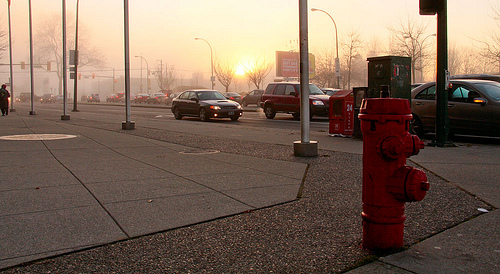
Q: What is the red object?
A: A fire hydrant.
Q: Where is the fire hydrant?
A: On the sidewalk.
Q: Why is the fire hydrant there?
A: For water to put out fires.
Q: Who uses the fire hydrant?
A: Firemen.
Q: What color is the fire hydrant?
A: Red.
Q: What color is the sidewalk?
A: Grey.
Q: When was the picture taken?
A: At sunrise.